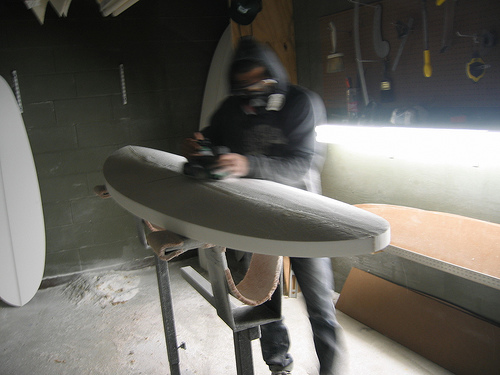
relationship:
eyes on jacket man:
[211, 60, 278, 83] [186, 35, 347, 375]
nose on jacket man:
[239, 72, 271, 94] [186, 35, 347, 375]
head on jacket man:
[208, 42, 311, 106] [186, 35, 347, 375]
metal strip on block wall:
[118, 63, 129, 106] [2, 10, 110, 278]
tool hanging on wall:
[323, 20, 343, 72] [315, 2, 498, 132]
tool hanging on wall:
[353, 0, 384, 105] [315, 2, 498, 132]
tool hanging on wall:
[377, 53, 394, 99] [315, 2, 498, 132]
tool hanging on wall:
[419, 2, 433, 78] [315, 2, 498, 132]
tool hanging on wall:
[457, 50, 491, 83] [315, 2, 498, 132]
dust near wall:
[63, 266, 138, 313] [4, 3, 183, 270]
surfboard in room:
[101, 144, 390, 258] [0, 1, 500, 375]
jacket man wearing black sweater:
[186, 35, 347, 375] [195, 38, 334, 178]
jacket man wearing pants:
[186, 35, 347, 375] [245, 178, 349, 373]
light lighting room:
[312, 123, 500, 159] [59, 27, 497, 350]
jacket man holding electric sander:
[186, 35, 347, 375] [183, 139, 230, 180]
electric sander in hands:
[183, 139, 230, 180] [216, 150, 248, 180]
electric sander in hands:
[183, 139, 230, 180] [187, 127, 207, 149]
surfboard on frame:
[101, 144, 390, 258] [146, 229, 282, 374]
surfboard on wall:
[0, 74, 47, 308] [2, 51, 132, 284]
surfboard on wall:
[1, 58, 47, 297] [0, 1, 230, 286]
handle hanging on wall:
[421, 47, 431, 75] [315, 2, 498, 132]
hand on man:
[213, 149, 256, 184] [182, 27, 361, 372]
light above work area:
[312, 115, 498, 172] [334, 201, 498, 372]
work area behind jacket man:
[283, 0, 494, 374] [186, 35, 347, 375]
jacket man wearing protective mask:
[186, 35, 347, 375] [233, 75, 278, 118]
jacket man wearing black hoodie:
[186, 35, 347, 375] [183, 35, 315, 194]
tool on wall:
[334, 2, 393, 113] [55, 52, 151, 123]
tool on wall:
[353, 0, 384, 105] [315, 2, 498, 132]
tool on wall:
[465, 51, 488, 82] [427, 24, 487, 116]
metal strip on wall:
[119, 64, 127, 105] [25, 25, 219, 253]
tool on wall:
[327, 22, 345, 73] [295, 10, 497, 223]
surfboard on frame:
[103, 144, 393, 374] [105, 236, 333, 372]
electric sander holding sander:
[183, 139, 230, 180] [185, 143, 225, 181]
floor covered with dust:
[1, 257, 448, 373] [66, 257, 148, 307]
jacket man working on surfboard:
[186, 35, 347, 375] [101, 144, 390, 258]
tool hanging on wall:
[366, 17, 396, 94] [271, 0, 496, 306]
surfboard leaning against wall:
[0, 74, 47, 308] [2, 0, 235, 261]